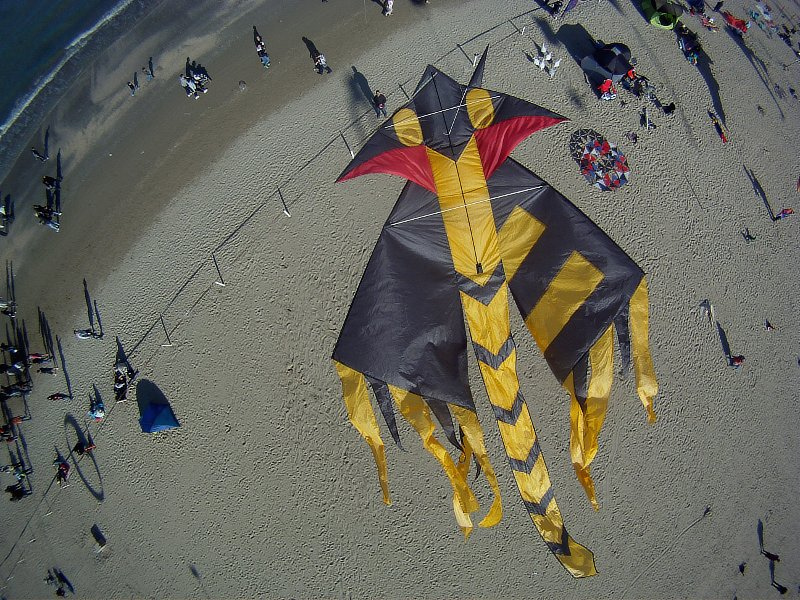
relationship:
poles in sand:
[170, 181, 311, 321] [1, 3, 774, 596]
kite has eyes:
[321, 40, 663, 588] [383, 82, 502, 150]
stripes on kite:
[463, 258, 604, 570] [302, 46, 747, 571]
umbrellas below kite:
[570, 121, 651, 202] [539, 116, 642, 228]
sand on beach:
[190, 357, 378, 558] [204, 386, 393, 576]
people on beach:
[16, 329, 131, 473] [18, 189, 292, 594]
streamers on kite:
[330, 357, 509, 529] [311, 344, 616, 597]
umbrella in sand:
[591, 35, 635, 78] [581, 107, 786, 252]